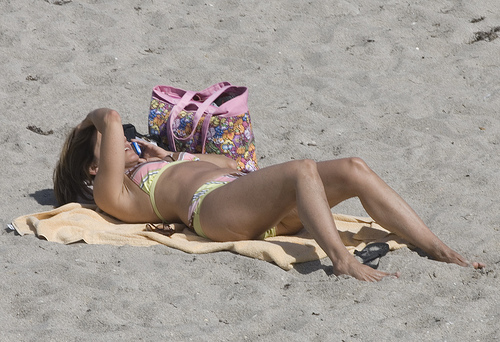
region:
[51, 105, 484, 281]
the lady is on the beach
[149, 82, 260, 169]
the purse is pink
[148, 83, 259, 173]
the purse has a floral design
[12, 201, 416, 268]
the blanket is orange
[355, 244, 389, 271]
the sandals are black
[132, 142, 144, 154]
the lady is on the phone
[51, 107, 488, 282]
the lady is wearing a bathing suit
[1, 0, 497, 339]
the lady is lying on the sand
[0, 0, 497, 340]
the lady is on the beach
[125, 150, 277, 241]
the bathing suit is pink and green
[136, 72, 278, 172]
bag is pink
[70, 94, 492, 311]
woman is tanning in the sand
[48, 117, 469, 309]
woman is pretty hot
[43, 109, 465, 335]
woman is lying in the sand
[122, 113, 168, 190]
woman's phone is blue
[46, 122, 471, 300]
hottie is sunbathing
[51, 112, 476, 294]
woman is on the phone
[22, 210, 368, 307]
towel is orange or creme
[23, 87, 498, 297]
beach is sandy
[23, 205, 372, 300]
towel keeps sand out of her vagina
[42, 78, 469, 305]
woman lies down on blanket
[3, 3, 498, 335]
sand is around woman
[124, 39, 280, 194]
woman has pink purse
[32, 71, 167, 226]
woman has straight hair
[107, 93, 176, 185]
woman talks on cellphone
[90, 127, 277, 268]
woman wears beach clothing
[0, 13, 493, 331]
sand is grey and black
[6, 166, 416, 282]
towel is bleached yellow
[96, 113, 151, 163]
woman opens mouth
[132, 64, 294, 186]
purse is pink and yellow and blue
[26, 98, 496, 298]
Woman lying on the beach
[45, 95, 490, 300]
Woman wears bikini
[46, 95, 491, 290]
Girl has her right hand on her head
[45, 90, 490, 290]
Girl is talking by phone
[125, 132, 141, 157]
Cell phone is blue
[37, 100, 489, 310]
Woman body is tan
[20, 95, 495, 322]
Woman lying on a towel color peach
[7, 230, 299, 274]
Beach towel is wrinkled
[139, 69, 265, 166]
Beach bag next to girl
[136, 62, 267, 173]
Handles of bag is pink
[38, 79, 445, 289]
woman laying on beach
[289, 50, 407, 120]
grey sand on beach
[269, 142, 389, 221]
bent knees of woman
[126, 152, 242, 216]
bikini on woman's body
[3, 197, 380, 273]
towel on beach sand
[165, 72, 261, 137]
pink handles on bag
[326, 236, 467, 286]
two feet in sand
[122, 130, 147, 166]
hand on phone against ear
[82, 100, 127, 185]
arm bent overhead touching hair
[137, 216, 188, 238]
sunglasses on towel next to hip